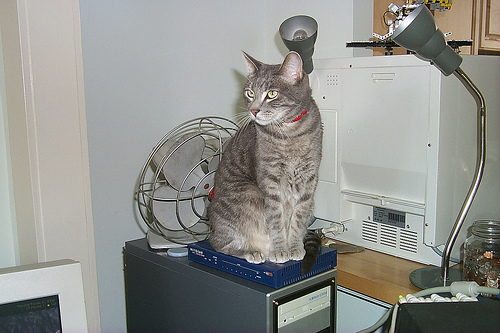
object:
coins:
[482, 252, 490, 258]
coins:
[475, 247, 487, 255]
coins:
[489, 265, 500, 275]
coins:
[478, 265, 491, 274]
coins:
[479, 264, 489, 273]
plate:
[373, 206, 405, 228]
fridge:
[299, 47, 499, 274]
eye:
[247, 90, 254, 99]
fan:
[133, 116, 240, 246]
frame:
[0, 257, 98, 333]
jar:
[458, 219, 500, 297]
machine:
[307, 53, 500, 269]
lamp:
[367, 3, 487, 297]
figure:
[367, 3, 434, 47]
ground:
[404, 137, 413, 169]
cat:
[206, 50, 324, 265]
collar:
[288, 109, 313, 121]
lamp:
[278, 15, 318, 74]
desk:
[322, 235, 462, 302]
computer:
[120, 238, 341, 331]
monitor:
[0, 258, 85, 333]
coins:
[467, 246, 483, 256]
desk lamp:
[278, 15, 320, 77]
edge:
[0, 251, 89, 275]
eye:
[265, 90, 278, 99]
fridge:
[313, 52, 498, 268]